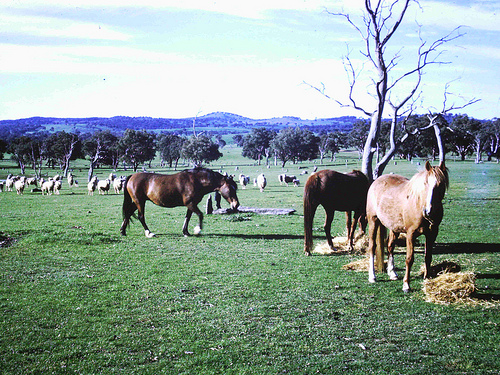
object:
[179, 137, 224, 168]
tree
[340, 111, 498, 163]
grove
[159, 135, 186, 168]
tree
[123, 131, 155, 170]
tree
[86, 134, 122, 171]
tree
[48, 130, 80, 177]
tree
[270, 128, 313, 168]
tree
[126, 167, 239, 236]
horse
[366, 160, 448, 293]
horse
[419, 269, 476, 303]
hay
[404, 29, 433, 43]
cloud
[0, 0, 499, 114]
sky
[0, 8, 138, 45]
cloud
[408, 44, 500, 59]
cloud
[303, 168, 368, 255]
horse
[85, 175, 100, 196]
sheep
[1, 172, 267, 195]
herd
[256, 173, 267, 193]
sheep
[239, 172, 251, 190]
sheep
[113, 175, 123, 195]
sheep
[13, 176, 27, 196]
sheep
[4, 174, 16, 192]
sheep